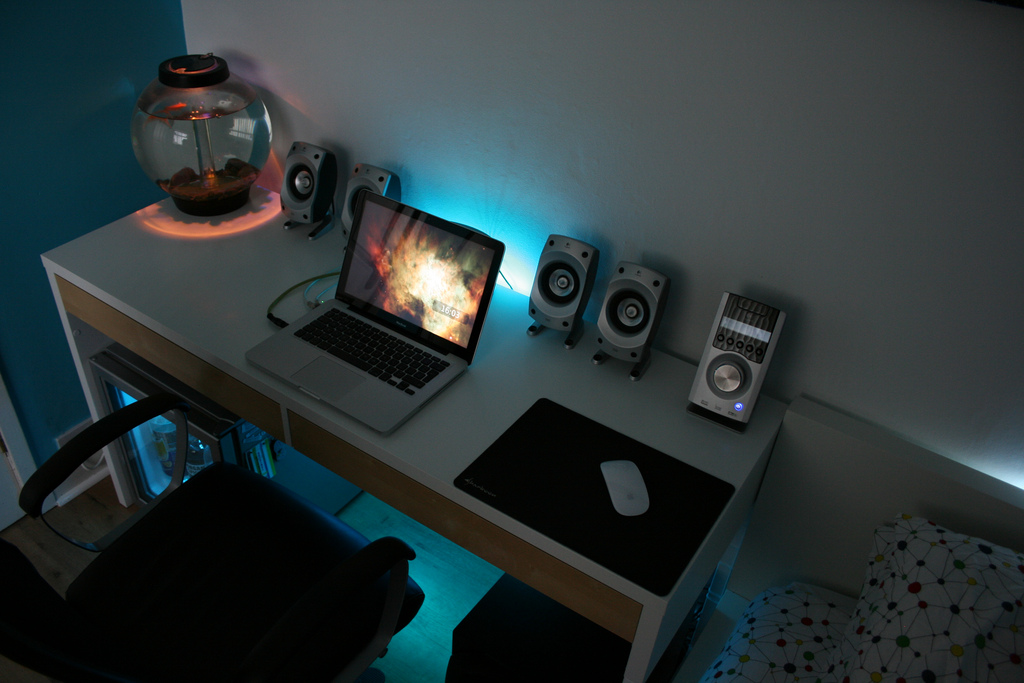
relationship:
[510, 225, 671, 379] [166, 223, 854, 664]
speakers on a desk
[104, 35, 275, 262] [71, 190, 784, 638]
aquarium sitting on a desk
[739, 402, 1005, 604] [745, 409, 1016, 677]
frame of a bed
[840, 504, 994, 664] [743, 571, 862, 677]
pillow on top of a mattress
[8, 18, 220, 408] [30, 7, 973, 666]
wall in a bedroom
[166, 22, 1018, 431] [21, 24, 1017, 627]
wall in a bedroom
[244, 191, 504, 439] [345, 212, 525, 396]
laptop with a screensaver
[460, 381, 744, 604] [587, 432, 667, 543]
mousepad with a mouse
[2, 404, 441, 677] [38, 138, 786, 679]
office chair in front of a desk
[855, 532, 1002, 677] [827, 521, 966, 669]
furniture and pillow case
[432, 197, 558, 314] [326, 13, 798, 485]
glow illuminating wall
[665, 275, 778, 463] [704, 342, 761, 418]
music player with dial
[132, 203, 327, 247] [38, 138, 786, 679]
glow on desk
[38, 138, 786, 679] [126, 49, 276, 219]
desk from aquarium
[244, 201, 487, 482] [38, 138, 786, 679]
laptop on a desk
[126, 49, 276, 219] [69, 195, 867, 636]
aquarium on a desk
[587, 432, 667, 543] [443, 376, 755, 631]
mouse on a mousepad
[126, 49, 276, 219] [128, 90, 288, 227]
aquarium has water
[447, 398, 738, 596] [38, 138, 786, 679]
mousepad on desk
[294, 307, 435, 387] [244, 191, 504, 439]
keys on a laptop